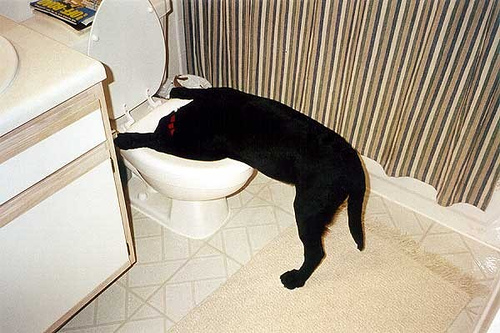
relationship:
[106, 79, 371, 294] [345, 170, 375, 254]
dog has tail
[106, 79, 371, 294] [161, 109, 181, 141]
dog has collar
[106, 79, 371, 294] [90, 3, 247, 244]
dog in toilet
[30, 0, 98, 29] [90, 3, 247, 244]
magazines on toilet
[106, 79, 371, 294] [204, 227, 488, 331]
dog on mat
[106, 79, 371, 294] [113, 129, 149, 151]
dog has paw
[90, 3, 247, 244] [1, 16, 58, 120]
toilet beside sink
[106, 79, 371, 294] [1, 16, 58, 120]
dog beside sink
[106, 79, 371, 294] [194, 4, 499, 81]
dog beside curtain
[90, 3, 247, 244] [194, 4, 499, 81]
toilet beside curtain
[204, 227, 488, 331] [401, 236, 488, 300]
mat has frills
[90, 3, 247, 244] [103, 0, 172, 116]
toilet has lid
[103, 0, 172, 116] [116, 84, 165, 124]
lid has hinges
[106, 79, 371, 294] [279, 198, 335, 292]
dog has hind leg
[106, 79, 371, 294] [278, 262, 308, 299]
dog has back paw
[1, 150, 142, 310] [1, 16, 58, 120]
cabinet under sink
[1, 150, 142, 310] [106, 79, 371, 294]
cabinet beside dog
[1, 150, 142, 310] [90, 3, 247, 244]
cabinet beside toilet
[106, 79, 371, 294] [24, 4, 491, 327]
dog in bathroom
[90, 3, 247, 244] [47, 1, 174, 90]
toilet has tank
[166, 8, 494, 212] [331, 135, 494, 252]
curtain of bathtub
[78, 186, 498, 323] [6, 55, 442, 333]
floor of bathroom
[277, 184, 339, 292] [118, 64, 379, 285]
leg of dog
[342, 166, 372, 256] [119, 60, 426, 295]
tail of dog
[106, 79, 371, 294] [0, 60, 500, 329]
dog in bathroom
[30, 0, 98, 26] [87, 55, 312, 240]
magazines on toilet